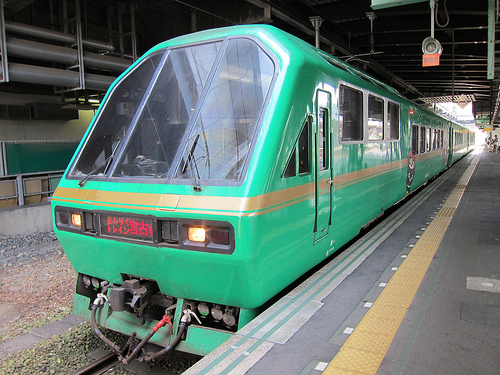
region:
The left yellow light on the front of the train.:
[72, 210, 77, 226]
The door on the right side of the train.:
[315, 89, 330, 240]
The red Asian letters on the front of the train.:
[105, 219, 153, 241]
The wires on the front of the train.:
[80, 284, 199, 361]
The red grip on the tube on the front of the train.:
[153, 315, 174, 337]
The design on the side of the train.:
[406, 149, 416, 194]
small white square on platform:
[309, 356, 332, 373]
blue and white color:
[232, 339, 260, 360]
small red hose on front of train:
[147, 312, 177, 339]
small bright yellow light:
[177, 222, 207, 247]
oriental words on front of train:
[98, 208, 160, 241]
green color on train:
[251, 242, 299, 284]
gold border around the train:
[193, 190, 273, 217]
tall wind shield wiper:
[174, 128, 217, 196]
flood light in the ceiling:
[404, 30, 453, 70]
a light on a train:
[63, 201, 84, 238]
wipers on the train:
[186, 134, 210, 189]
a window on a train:
[355, 96, 396, 138]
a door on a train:
[304, 119, 346, 205]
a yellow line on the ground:
[357, 305, 409, 356]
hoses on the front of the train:
[137, 313, 200, 358]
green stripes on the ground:
[252, 316, 294, 345]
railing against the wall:
[10, 167, 39, 207]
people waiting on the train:
[481, 128, 499, 158]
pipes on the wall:
[30, 31, 79, 100]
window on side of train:
[336, 81, 365, 142]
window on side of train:
[366, 90, 384, 140]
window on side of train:
[386, 98, 398, 141]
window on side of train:
[411, 125, 418, 154]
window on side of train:
[419, 125, 427, 151]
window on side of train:
[425, 127, 430, 152]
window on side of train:
[431, 128, 434, 150]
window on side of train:
[435, 130, 440, 147]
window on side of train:
[440, 127, 445, 152]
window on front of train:
[112, 36, 229, 186]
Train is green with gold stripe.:
[49, 23, 475, 357]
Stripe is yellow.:
[323, 145, 487, 373]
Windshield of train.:
[67, 35, 278, 187]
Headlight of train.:
[57, 206, 231, 249]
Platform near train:
[184, 146, 499, 373]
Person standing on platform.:
[493, 135, 499, 153]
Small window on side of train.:
[334, 79, 366, 144]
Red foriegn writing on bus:
[104, 215, 154, 238]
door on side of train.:
[313, 89, 335, 241]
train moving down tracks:
[22, 17, 494, 368]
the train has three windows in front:
[8, 12, 483, 372]